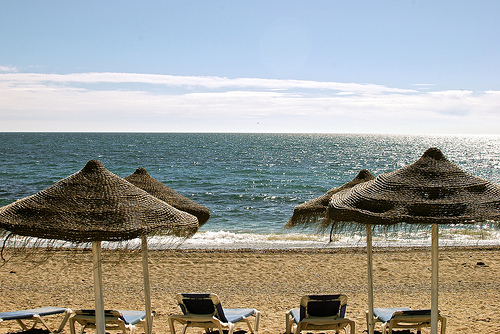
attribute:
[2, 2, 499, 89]
sky — crisp, clear, blue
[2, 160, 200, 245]
umbrella — brown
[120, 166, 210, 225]
umbrella — brown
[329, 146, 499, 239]
umbrella — brown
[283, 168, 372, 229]
umbrella — brown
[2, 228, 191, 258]
fringes — long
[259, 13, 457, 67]
sky — clear, blue, distance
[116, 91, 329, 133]
clouds — white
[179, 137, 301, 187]
water — blue, deep, ocean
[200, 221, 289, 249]
waves — small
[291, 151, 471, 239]
umbrellas — beach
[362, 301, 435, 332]
chair — blue, lounge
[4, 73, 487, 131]
clouds — wispy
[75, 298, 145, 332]
chair — laid, back, beach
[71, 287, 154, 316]
beach — empty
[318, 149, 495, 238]
umbrella — straw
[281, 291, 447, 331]
chairs — fold up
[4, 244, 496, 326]
sand — brown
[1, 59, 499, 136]
clouds — long, wispy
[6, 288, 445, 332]
chairs — brown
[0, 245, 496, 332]
ground — brown, dark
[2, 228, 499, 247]
waves — white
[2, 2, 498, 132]
sky — white, blue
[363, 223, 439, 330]
poles — brown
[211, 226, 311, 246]
waves — small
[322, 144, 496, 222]
umbrella — brown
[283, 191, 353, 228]
umbrella — brown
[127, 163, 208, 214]
umbrella — brown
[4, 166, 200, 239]
umbrella — brown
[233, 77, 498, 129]
clouds — wispy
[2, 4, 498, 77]
sky — blue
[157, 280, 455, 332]
chairs — lounge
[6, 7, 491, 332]
sun — hot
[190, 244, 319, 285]
beach — sundy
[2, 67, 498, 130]
clouds — white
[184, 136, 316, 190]
water — blue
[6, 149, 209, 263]
umbrella — open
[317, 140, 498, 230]
umbrella — open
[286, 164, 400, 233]
umbrella — large, open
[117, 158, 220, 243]
umbrella — large, open